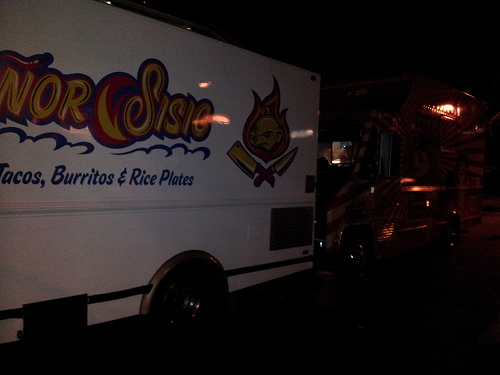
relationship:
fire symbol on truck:
[244, 76, 309, 166] [3, 2, 341, 319]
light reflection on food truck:
[423, 100, 440, 117] [320, 64, 492, 244]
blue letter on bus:
[0, 161, 195, 187] [1, 1, 423, 356]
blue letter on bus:
[1, 165, 197, 189] [1, 0, 324, 352]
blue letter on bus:
[0, 161, 195, 187] [0, 0, 326, 350]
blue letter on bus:
[0, 161, 195, 187] [78, 46, 429, 351]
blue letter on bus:
[0, 161, 195, 187] [316, 88, 488, 277]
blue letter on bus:
[0, 161, 195, 187] [0, 58, 345, 355]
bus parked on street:
[1, 0, 324, 352] [245, 208, 490, 373]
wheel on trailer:
[147, 269, 230, 354] [1, 0, 458, 362]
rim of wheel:
[180, 295, 210, 327] [146, 266, 227, 351]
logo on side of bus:
[0, 47, 224, 155] [1, 0, 324, 352]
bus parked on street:
[1, 0, 324, 352] [43, 216, 495, 372]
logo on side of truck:
[0, 51, 212, 148] [1, 24, 356, 330]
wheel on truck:
[144, 259, 231, 374] [3, 3, 497, 361]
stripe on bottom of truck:
[231, 249, 319, 286] [0, 4, 325, 351]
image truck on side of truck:
[224, 77, 296, 204] [3, 3, 497, 361]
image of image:
[223, 142, 300, 188] [223, 142, 300, 188]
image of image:
[227, 71, 301, 188] [223, 142, 300, 188]